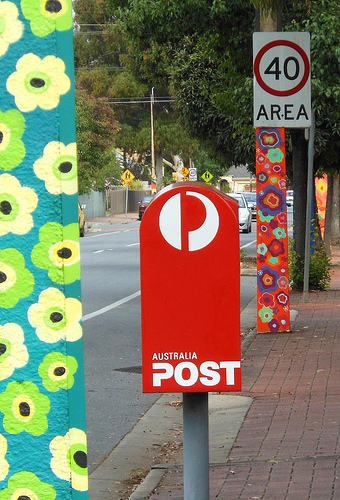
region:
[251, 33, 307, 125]
a white sign with a red circle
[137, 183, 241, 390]
a red sign with white lettering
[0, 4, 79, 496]
a painted blue post with flowers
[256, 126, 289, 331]
A painted red post with flowers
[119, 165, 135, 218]
a yellow street sign on a post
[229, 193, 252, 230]
front end of a white car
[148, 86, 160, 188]
an electric utility pole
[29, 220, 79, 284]
a green flower with a black center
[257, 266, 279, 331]
colorful painted flowers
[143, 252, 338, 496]
a brick paved side walk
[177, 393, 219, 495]
a post on the sidewalk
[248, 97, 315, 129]
black letters on a sign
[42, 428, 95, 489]
a floral pattern print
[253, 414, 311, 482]
sidewalk made of bricks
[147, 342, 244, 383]
white letters on a sign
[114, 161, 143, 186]
a yellow sign on a post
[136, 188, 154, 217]
a car parked beside the street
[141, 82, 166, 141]
a power pole beside the street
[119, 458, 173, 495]
a curb between the street and sidewalk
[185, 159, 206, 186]
a white sign in the distance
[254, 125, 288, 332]
orange fabric banner under sign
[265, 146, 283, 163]
blue flower on banner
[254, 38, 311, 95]
red circle on white sign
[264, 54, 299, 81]
black numbers inside circle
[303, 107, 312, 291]
gray metal pole behind sign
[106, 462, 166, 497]
curb next to banner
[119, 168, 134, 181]
yellow diamond shaped sign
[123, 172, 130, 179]
black graphic on yellow sign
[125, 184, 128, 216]
metal post under yellow sign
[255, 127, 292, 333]
banner touching sidewalk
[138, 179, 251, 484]
an australia post box beside the road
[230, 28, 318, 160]
a sign on the street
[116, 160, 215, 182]
a street signs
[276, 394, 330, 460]
a brick sidewalk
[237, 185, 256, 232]
cars on the road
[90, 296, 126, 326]
a solid white paint on the road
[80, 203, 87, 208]
a side window of the partially visible vehicle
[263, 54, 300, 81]
a number 40 on a sign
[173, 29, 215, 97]
leaves on the branches of a tree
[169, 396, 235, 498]
a post supporting the Australia Post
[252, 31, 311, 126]
A sign posting the speed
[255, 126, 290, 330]
A brightly colored pole with flowers on it.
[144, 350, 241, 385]
The words Australia Post in white.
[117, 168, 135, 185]
A yellow pedestrian sign in the background.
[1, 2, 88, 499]
A aqua colored pole with green and yellow flowers.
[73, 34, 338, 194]
Large green trees overhanging the street.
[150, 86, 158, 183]
A light pole in the background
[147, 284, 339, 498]
A red brick sidewalk.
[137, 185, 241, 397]
An Australia red post box.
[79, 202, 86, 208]
The mirror on the side of a yellow car.